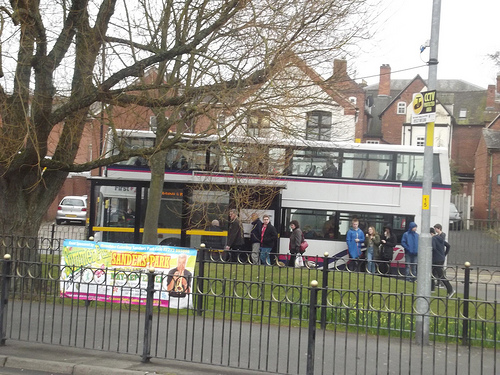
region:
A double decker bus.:
[91, 125, 458, 280]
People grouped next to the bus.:
[191, 203, 455, 291]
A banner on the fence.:
[55, 235, 205, 315]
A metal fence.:
[6, 230, 496, 373]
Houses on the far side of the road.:
[8, 50, 499, 232]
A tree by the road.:
[6, 0, 326, 316]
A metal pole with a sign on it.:
[403, 3, 445, 338]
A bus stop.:
[81, 173, 292, 265]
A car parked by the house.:
[53, 191, 93, 232]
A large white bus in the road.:
[88, 123, 458, 280]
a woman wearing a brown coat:
[287, 220, 307, 272]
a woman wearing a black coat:
[260, 212, 275, 264]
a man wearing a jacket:
[223, 208, 241, 260]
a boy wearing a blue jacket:
[343, 217, 362, 263]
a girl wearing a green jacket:
[365, 226, 381, 281]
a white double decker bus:
[92, 125, 448, 276]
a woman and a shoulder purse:
[286, 219, 307, 276]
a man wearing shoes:
[428, 226, 453, 301]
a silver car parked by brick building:
[56, 193, 87, 227]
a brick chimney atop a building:
[378, 63, 391, 88]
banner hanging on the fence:
[57, 231, 199, 312]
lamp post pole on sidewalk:
[406, 1, 444, 349]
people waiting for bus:
[225, 204, 455, 294]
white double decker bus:
[97, 124, 454, 282]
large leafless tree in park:
[0, 0, 373, 304]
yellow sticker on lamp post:
[421, 190, 428, 210]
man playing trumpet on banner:
[162, 250, 192, 305]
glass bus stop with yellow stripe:
[85, 170, 233, 256]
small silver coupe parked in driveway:
[55, 192, 85, 222]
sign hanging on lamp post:
[410, 87, 435, 121]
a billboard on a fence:
[57, 229, 208, 319]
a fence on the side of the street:
[5, 226, 495, 370]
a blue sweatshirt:
[345, 222, 365, 255]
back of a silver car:
[53, 190, 95, 228]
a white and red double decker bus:
[83, 128, 467, 286]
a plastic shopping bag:
[291, 250, 307, 272]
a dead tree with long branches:
[2, 2, 334, 287]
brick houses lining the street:
[7, 58, 498, 238]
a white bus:
[103, 121, 458, 281]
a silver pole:
[420, 5, 436, 331]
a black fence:
[6, 260, 406, 370]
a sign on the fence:
[55, 235, 202, 315]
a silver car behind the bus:
[51, 187, 87, 214]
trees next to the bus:
[6, 0, 166, 270]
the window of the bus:
[285, 150, 420, 180]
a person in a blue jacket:
[345, 212, 365, 257]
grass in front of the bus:
[210, 260, 420, 315]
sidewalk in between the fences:
[7, 292, 485, 372]